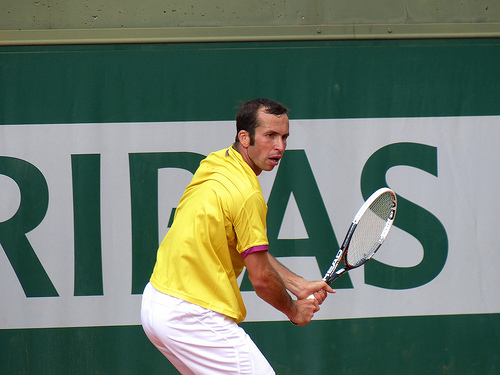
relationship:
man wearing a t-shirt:
[133, 94, 336, 374] [150, 152, 266, 319]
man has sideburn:
[133, 94, 336, 374] [247, 127, 260, 147]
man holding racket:
[133, 94, 336, 374] [310, 178, 411, 301]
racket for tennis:
[310, 178, 411, 301] [367, 220, 368, 235]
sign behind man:
[2, 120, 496, 326] [133, 94, 336, 374]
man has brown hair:
[133, 94, 336, 374] [224, 97, 288, 135]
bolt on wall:
[314, 28, 325, 35] [3, 2, 497, 371]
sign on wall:
[2, 120, 496, 326] [3, 2, 497, 371]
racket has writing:
[310, 178, 411, 301] [323, 247, 342, 281]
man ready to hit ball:
[133, 94, 336, 374] [445, 364, 446, 365]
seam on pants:
[194, 314, 259, 375] [138, 290, 273, 375]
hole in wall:
[91, 14, 101, 22] [3, 2, 497, 371]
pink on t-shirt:
[239, 244, 271, 253] [150, 152, 266, 319]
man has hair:
[133, 94, 336, 374] [224, 97, 288, 135]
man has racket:
[133, 94, 336, 374] [310, 178, 411, 301]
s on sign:
[355, 141, 459, 283] [2, 120, 496, 326]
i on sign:
[66, 147, 115, 300] [2, 120, 496, 326]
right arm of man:
[235, 190, 318, 343] [133, 94, 336, 374]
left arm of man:
[271, 249, 324, 290] [133, 94, 336, 374]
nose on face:
[273, 137, 288, 153] [251, 121, 292, 177]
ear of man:
[237, 126, 252, 149] [133, 94, 336, 374]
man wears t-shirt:
[133, 94, 336, 374] [150, 152, 266, 319]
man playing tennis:
[133, 94, 336, 374] [367, 220, 368, 235]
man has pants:
[133, 94, 336, 374] [138, 290, 273, 375]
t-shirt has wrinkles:
[150, 152, 266, 319] [189, 154, 236, 192]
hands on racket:
[291, 280, 329, 329] [310, 178, 411, 301]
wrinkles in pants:
[171, 325, 213, 374] [138, 290, 273, 375]